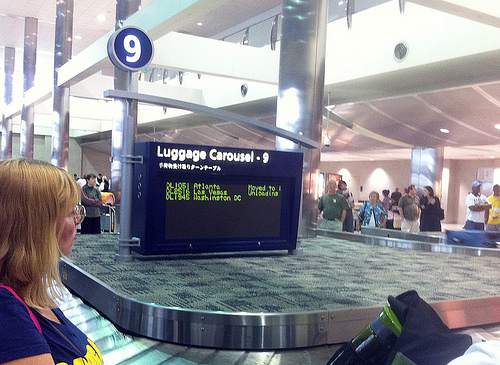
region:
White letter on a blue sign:
[153, 145, 163, 162]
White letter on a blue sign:
[161, 145, 173, 161]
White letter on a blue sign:
[168, 144, 178, 162]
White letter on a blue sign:
[178, 144, 185, 166]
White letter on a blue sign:
[186, 145, 190, 167]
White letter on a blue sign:
[192, 144, 201, 166]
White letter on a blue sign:
[196, 148, 206, 163]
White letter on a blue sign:
[205, 145, 215, 162]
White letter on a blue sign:
[213, 148, 221, 168]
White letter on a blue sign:
[219, 148, 226, 164]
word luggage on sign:
[150, 140, 207, 160]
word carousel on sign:
[210, 143, 255, 166]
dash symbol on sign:
[256, 153, 263, 164]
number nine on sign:
[260, 151, 270, 164]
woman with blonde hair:
[11, 189, 38, 224]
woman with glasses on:
[71, 204, 86, 226]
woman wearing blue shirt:
[55, 324, 70, 345]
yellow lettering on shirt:
[80, 353, 101, 363]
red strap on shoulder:
[8, 289, 24, 306]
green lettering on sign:
[163, 180, 286, 205]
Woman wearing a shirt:
[0, 267, 110, 363]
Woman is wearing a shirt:
[0, 267, 109, 363]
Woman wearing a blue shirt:
[0, 271, 112, 363]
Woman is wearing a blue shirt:
[0, 270, 108, 363]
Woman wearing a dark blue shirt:
[0, 268, 107, 363]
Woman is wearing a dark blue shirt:
[1, 267, 107, 364]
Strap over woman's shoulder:
[0, 277, 55, 344]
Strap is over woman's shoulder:
[0, 273, 55, 341]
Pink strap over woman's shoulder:
[0, 277, 51, 343]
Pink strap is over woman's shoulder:
[0, 277, 53, 342]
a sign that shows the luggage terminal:
[97, 126, 304, 274]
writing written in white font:
[145, 126, 283, 178]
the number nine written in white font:
[251, 146, 281, 174]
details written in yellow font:
[160, 169, 294, 221]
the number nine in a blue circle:
[97, 18, 168, 79]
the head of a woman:
[0, 162, 92, 326]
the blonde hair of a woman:
[14, 173, 49, 251]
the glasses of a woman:
[55, 196, 96, 224]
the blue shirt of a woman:
[21, 293, 81, 363]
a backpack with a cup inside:
[361, 283, 461, 354]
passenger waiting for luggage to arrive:
[2, 144, 135, 364]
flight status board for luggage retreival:
[123, 135, 315, 261]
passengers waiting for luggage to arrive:
[318, 170, 499, 244]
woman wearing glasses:
[56, 197, 95, 259]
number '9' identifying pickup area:
[101, 17, 159, 79]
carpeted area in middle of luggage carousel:
[66, 233, 496, 317]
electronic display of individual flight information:
[160, 176, 293, 210]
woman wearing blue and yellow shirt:
[3, 278, 110, 363]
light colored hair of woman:
[4, 152, 86, 312]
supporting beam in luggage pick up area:
[269, 8, 341, 240]